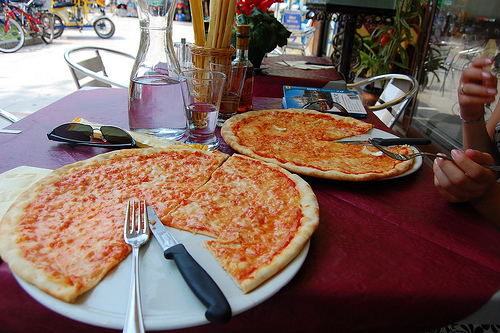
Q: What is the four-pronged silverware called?
A: A fork.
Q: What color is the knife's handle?
A: Black.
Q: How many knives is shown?
A: 1.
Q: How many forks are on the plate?
A: One.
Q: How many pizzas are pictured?
A: 2.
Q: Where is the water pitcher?
A: On the middle of the table.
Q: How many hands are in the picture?
A: Two.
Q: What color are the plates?
A: White.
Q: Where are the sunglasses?
A: On the table in front of the pizza.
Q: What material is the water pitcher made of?
A: Glass.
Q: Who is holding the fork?
A: A woman.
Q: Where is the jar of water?
A: On the table.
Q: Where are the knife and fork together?
A: On the plate.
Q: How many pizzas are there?
A: Two.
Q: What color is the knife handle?
A: Black.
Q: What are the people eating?
A: Pizza.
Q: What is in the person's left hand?
A: A fork.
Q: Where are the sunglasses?
A: Above the front pizza.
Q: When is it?
A: Daytime.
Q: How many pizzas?
A: Two.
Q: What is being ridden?
A: Bicycle.